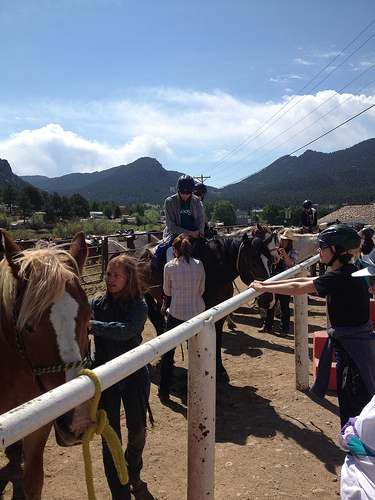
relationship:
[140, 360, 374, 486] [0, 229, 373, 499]
shade on ground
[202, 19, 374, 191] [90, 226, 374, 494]
wire above crowd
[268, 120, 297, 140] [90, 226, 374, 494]
wire above crowd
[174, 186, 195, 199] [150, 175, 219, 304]
glasses on person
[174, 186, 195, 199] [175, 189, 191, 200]
glasses on face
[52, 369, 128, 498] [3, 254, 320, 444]
rope wrapped around pole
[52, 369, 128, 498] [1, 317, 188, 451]
rope wrapped around white pole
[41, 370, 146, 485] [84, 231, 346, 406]
rope wrapped around white pole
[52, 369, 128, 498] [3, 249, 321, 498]
rope wrapped around pole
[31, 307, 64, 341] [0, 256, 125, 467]
eye of horse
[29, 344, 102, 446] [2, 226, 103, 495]
nose of horse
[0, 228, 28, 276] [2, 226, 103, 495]
ear of horse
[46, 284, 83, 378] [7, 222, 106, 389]
marking on head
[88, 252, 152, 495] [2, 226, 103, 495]
girl next to horse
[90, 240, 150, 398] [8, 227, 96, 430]
girl standing next to horse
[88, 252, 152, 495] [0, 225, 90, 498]
girl standing next to horse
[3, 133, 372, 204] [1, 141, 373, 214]
hills in background